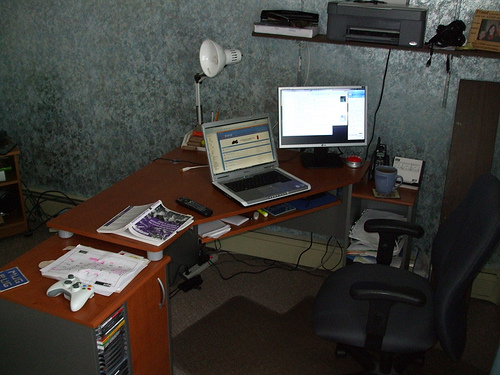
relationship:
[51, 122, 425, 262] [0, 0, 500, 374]
corner desk in room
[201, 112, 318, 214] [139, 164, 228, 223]
laptop on desk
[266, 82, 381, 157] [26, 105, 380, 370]
monitor on side of desk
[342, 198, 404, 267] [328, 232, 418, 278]
papers are stacked on a shelf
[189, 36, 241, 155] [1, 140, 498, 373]
white lamp on desk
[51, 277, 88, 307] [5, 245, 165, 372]
controller sitting near a file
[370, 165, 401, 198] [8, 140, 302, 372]
cup on desk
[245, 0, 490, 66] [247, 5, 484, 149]
shelf on wall